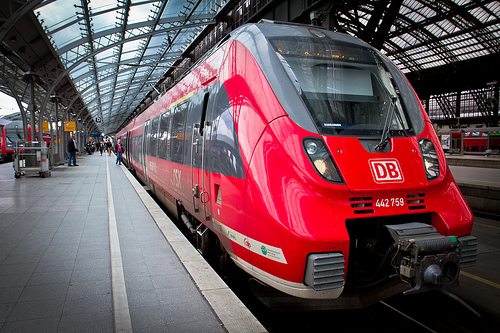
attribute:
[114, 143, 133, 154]
shirt — red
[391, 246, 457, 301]
connector — black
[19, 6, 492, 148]
sun roof — glass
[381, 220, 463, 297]
motor — electric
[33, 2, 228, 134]
windows — glass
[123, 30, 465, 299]
train — red, gray, passenger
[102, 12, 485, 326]
train — red, black, grey, white, gray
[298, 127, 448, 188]
lights — train, not turned on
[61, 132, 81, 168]
person — looking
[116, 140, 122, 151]
shirt — red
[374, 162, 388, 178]
letter — red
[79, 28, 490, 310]
train — not moving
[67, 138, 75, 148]
shirt — black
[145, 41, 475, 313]
passenger train — red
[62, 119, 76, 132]
sign — yellow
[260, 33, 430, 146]
window — clean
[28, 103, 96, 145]
signs — yellow